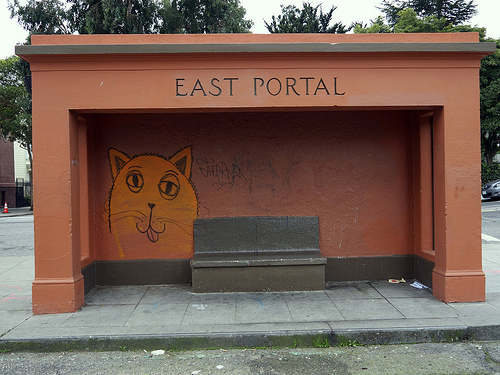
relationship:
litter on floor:
[382, 273, 429, 293] [2, 295, 498, 368]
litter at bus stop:
[382, 273, 429, 293] [17, 31, 488, 308]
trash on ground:
[388, 263, 435, 295] [7, 262, 485, 345]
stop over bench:
[12, 15, 498, 342] [191, 216, 326, 293]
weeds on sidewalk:
[309, 334, 362, 349] [0, 240, 499, 341]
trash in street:
[145, 346, 235, 373] [2, 322, 497, 373]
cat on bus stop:
[102, 142, 215, 266] [17, 31, 488, 308]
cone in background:
[1, 198, 11, 215] [5, 5, 497, 227]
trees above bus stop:
[2, 1, 498, 200] [17, 31, 488, 308]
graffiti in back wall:
[184, 147, 250, 194] [81, 107, 417, 283]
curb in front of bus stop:
[6, 330, 486, 350] [17, 31, 488, 308]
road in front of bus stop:
[51, 342, 447, 370] [17, 31, 488, 308]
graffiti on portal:
[210, 144, 352, 194] [16, 28, 484, 310]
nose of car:
[482, 182, 492, 199] [483, 175, 499, 200]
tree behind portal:
[0, 53, 33, 177] [16, 28, 484, 310]